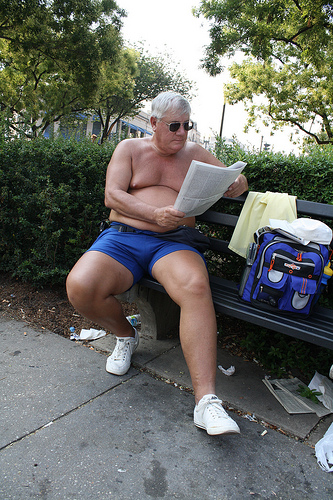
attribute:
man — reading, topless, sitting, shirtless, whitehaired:
[65, 90, 249, 437]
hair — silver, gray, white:
[149, 89, 189, 117]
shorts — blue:
[85, 220, 207, 284]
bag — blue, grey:
[239, 219, 328, 318]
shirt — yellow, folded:
[226, 189, 298, 259]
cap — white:
[271, 218, 331, 244]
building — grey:
[9, 87, 153, 139]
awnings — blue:
[47, 111, 147, 136]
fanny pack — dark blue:
[102, 220, 210, 249]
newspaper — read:
[171, 158, 249, 219]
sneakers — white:
[103, 335, 243, 440]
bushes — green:
[1, 141, 332, 370]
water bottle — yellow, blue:
[321, 258, 333, 285]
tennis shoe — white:
[191, 393, 238, 435]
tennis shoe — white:
[105, 332, 142, 375]